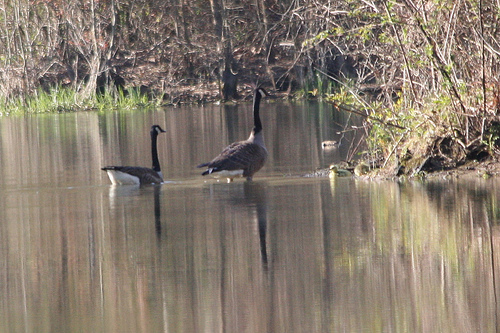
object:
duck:
[325, 161, 352, 183]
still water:
[0, 95, 500, 332]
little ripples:
[168, 177, 206, 186]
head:
[148, 122, 169, 135]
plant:
[306, 0, 500, 172]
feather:
[205, 165, 219, 177]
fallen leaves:
[128, 62, 158, 84]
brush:
[279, 1, 499, 177]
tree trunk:
[208, 0, 242, 104]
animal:
[197, 85, 277, 182]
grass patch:
[0, 77, 160, 118]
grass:
[0, 82, 171, 116]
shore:
[1, 80, 400, 119]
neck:
[250, 97, 263, 143]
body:
[100, 133, 163, 186]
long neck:
[252, 95, 265, 133]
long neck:
[148, 132, 160, 169]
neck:
[148, 133, 161, 169]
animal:
[101, 124, 169, 185]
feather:
[109, 170, 118, 179]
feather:
[142, 172, 159, 181]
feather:
[123, 169, 138, 176]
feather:
[137, 169, 152, 173]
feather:
[151, 156, 159, 165]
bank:
[0, 0, 389, 117]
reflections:
[198, 179, 287, 273]